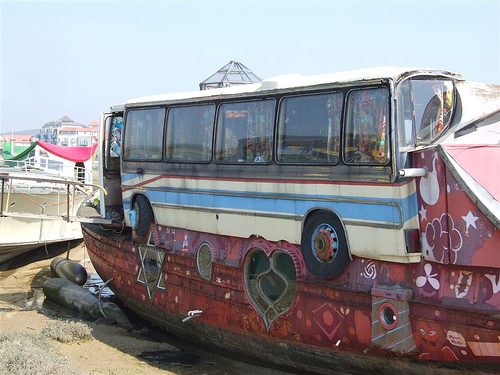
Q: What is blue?
A: Sky.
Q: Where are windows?
A: On a bus.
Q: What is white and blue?
A: Bus.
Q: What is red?
A: Boat.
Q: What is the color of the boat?
A: Red.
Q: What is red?
A: The boat.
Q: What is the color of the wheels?
A: Black.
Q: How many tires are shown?
A: Two.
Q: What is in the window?
A: Curtains.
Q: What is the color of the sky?
A: Blue.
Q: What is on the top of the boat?
A: A bus.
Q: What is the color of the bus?
A: Blue and white.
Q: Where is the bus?
A: On the top of the boat.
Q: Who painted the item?
A: Hippies.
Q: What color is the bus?
A: Red, white, and blue.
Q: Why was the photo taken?
A: To show the interesting object.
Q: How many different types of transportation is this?
A: 2.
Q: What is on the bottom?
A: A boat.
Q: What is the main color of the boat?
A: Pink.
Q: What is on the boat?
A: A bus.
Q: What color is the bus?
A: White, red, and blue.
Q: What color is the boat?
A: Red.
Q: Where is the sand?
A: Next to the boat.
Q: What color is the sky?
A: Blue.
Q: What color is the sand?
A: Brown.